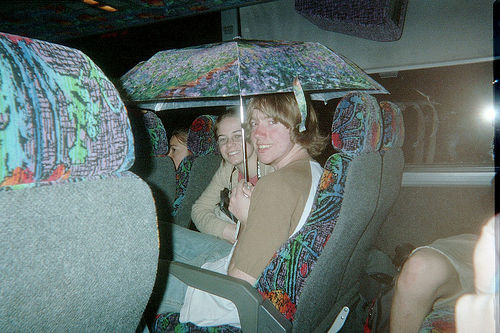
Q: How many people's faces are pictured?
A: Three.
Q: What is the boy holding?
A: Umbrella.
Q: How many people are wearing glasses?
A: None.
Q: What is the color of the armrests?
A: Grey.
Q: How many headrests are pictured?
A: Five.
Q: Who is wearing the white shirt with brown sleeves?
A: The boy.